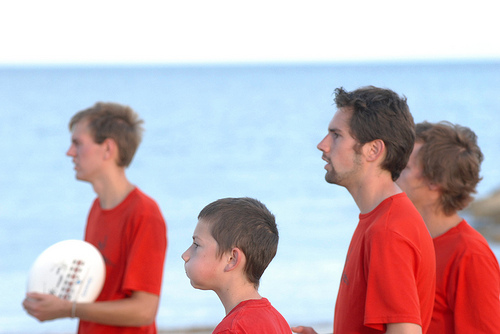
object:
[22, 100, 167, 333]
male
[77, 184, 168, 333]
shirt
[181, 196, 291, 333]
male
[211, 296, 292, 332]
shirt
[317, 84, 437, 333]
male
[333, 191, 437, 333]
shirt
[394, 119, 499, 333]
male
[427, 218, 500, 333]
shirt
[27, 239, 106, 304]
frisbee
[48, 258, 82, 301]
lettering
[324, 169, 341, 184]
goatee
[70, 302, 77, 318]
watch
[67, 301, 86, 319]
wrist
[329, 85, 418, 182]
hair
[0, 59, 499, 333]
water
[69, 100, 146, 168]
hair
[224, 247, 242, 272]
ear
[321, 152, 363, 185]
facial hair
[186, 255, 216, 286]
cheek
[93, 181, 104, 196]
adam's apple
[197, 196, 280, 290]
hair